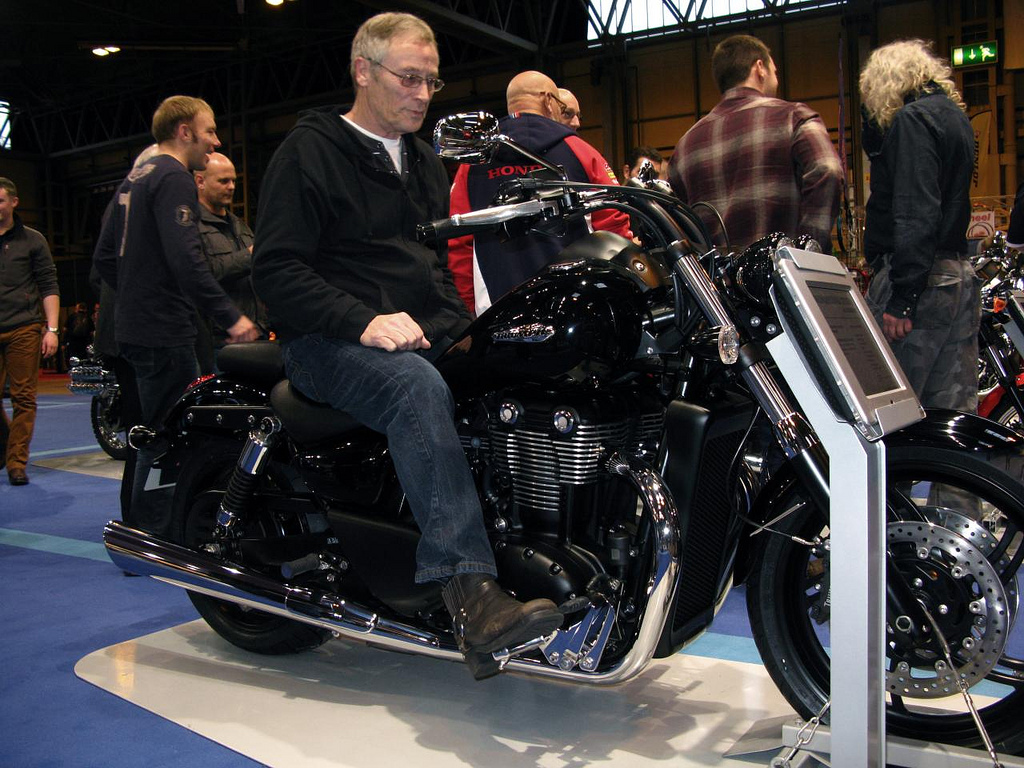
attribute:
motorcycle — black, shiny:
[115, 104, 1021, 757]